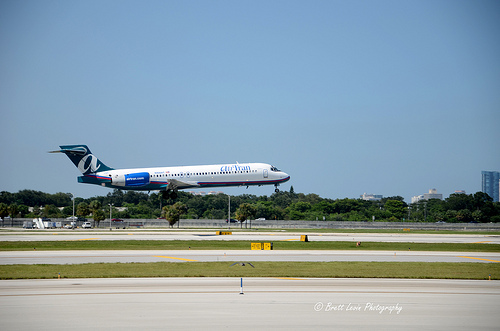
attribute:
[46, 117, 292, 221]
airplane — taking flight, long, commercial, for passengers, white, flying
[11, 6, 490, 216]
sky — blue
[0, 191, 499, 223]
trees — tall, green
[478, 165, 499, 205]
skyscraper — gray, large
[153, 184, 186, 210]
landing gear — out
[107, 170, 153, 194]
engine — white, blue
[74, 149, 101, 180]
letter — white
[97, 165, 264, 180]
windows — square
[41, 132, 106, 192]
tail — gray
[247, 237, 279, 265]
squares — yellow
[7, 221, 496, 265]
runway — gray, empty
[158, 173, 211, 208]
wing — white, triangular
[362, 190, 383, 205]
building — gray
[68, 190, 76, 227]
pole — silver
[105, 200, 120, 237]
pole — silver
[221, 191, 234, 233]
pole — silver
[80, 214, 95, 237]
car — white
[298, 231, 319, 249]
block — triangular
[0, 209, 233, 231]
fence — metal